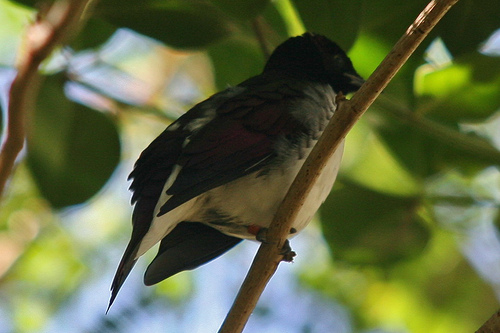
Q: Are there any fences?
A: No, there are no fences.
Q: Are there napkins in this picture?
A: No, there are no napkins.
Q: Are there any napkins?
A: No, there are no napkins.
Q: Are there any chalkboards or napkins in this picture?
A: No, there are no napkins or chalkboards.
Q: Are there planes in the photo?
A: No, there are no planes.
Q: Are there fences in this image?
A: No, there are no fences.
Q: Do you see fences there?
A: No, there are no fences.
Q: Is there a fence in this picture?
A: No, there are no fences.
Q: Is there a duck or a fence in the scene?
A: No, there are no fences or ducks.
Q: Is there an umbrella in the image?
A: No, there are no umbrellas.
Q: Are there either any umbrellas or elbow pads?
A: No, there are no umbrellas or elbow pads.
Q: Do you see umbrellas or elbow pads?
A: No, there are no umbrellas or elbow pads.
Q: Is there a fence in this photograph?
A: No, there are no fences.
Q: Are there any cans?
A: No, there are no cans.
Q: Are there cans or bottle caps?
A: No, there are no cans or bottle caps.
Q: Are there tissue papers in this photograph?
A: No, there are no tissue papers.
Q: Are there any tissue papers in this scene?
A: No, there are no tissue papers.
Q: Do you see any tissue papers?
A: No, there are no tissue papers.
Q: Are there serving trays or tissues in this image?
A: No, there are no tissues or serving trays.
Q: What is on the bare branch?
A: The leaves are on the branch.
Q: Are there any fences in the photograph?
A: No, there are no fences.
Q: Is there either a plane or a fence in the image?
A: No, there are no fences or airplanes.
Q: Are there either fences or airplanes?
A: No, there are no fences or airplanes.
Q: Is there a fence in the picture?
A: No, there are no fences.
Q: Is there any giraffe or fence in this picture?
A: No, there are no fences or giraffes.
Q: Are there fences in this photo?
A: No, there are no fences.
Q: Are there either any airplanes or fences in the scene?
A: No, there are no fences or airplanes.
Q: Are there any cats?
A: No, there are no cats.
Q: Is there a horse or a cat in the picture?
A: No, there are no cats or horses.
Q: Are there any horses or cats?
A: No, there are no cats or horses.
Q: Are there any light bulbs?
A: No, there are no light bulbs.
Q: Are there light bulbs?
A: No, there are no light bulbs.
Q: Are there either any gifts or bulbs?
A: No, there are no bulbs or gifts.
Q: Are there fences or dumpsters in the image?
A: No, there are no fences or dumpsters.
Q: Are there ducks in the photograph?
A: No, there are no ducks.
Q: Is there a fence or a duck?
A: No, there are no ducks or fences.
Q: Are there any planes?
A: No, there are no planes.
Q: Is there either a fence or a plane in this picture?
A: No, there are no airplanes or fences.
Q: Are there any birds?
A: Yes, there is a bird.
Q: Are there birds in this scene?
A: Yes, there is a bird.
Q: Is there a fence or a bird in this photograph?
A: Yes, there is a bird.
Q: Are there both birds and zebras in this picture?
A: No, there is a bird but no zebras.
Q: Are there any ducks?
A: No, there are no ducks.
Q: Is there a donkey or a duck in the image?
A: No, there are no ducks or donkeys.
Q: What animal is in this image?
A: The animal is a bird.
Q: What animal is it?
A: The animal is a bird.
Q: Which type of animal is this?
A: This is a bird.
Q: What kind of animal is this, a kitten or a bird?
A: This is a bird.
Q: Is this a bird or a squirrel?
A: This is a bird.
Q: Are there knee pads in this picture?
A: No, there are no knee pads.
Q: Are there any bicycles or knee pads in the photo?
A: No, there are no knee pads or bicycles.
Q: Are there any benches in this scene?
A: No, there are no benches.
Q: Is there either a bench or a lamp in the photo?
A: No, there are no benches or lamps.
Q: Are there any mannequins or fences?
A: No, there are no fences or mannequins.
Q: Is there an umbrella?
A: No, there are no umbrellas.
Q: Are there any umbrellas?
A: No, there are no umbrellas.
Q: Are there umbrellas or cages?
A: No, there are no umbrellas or cages.